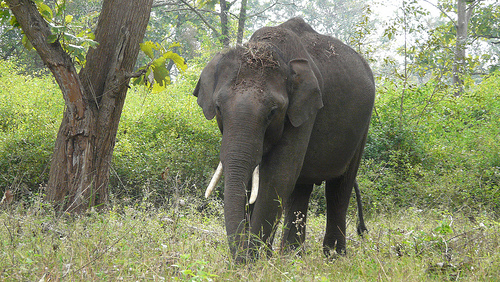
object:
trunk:
[220, 92, 264, 265]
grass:
[0, 61, 496, 278]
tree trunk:
[49, 0, 153, 214]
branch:
[7, 0, 87, 112]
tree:
[0, 0, 190, 216]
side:
[306, 33, 378, 181]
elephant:
[189, 15, 379, 265]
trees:
[451, 0, 469, 98]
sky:
[213, 0, 499, 86]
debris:
[232, 30, 287, 92]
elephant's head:
[191, 25, 326, 267]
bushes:
[479, 176, 495, 210]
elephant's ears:
[191, 46, 244, 121]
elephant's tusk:
[203, 160, 261, 206]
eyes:
[266, 106, 281, 122]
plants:
[4, 244, 11, 280]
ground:
[0, 185, 497, 280]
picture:
[0, 0, 500, 282]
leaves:
[148, 55, 159, 62]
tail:
[352, 176, 370, 239]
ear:
[286, 58, 324, 129]